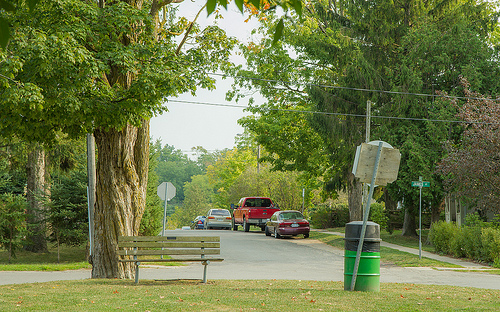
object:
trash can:
[344, 219, 383, 293]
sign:
[408, 179, 432, 188]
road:
[1, 265, 499, 290]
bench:
[117, 235, 223, 283]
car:
[264, 210, 313, 242]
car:
[230, 196, 280, 232]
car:
[206, 208, 234, 230]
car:
[191, 213, 207, 230]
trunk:
[92, 129, 149, 278]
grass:
[2, 279, 499, 311]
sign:
[350, 138, 400, 189]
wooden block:
[354, 142, 401, 189]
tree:
[432, 73, 499, 215]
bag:
[343, 239, 380, 254]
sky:
[144, 0, 321, 165]